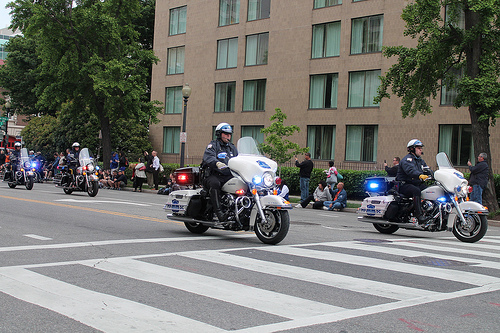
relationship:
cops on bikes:
[17, 117, 446, 199] [12, 147, 493, 247]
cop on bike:
[197, 115, 245, 226] [168, 154, 305, 248]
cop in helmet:
[197, 115, 245, 226] [212, 120, 237, 135]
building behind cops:
[147, 0, 499, 201] [17, 117, 446, 199]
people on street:
[31, 150, 355, 203] [1, 175, 500, 330]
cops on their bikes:
[17, 117, 446, 199] [12, 147, 493, 247]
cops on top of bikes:
[17, 117, 446, 199] [12, 147, 493, 247]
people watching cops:
[31, 150, 355, 203] [17, 117, 446, 199]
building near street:
[147, 0, 499, 201] [1, 175, 500, 330]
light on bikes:
[366, 178, 385, 193] [12, 147, 493, 247]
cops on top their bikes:
[17, 117, 446, 199] [12, 147, 493, 247]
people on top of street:
[31, 150, 355, 203] [1, 175, 500, 330]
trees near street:
[16, 7, 492, 170] [1, 175, 500, 330]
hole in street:
[349, 229, 466, 286] [1, 175, 500, 330]